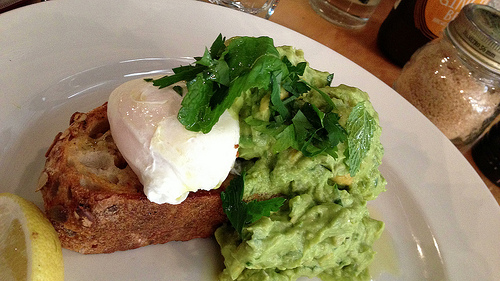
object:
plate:
[0, 0, 499, 281]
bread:
[35, 102, 230, 256]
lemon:
[0, 191, 64, 281]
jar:
[390, 3, 499, 155]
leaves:
[219, 49, 284, 95]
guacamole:
[303, 216, 334, 242]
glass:
[310, 0, 376, 30]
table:
[356, 48, 367, 60]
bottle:
[376, 0, 499, 69]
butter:
[107, 74, 242, 205]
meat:
[272, 204, 327, 237]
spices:
[449, 107, 480, 129]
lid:
[446, 3, 499, 75]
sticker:
[422, 0, 488, 39]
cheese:
[441, 60, 478, 85]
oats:
[89, 125, 101, 140]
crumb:
[233, 144, 241, 154]